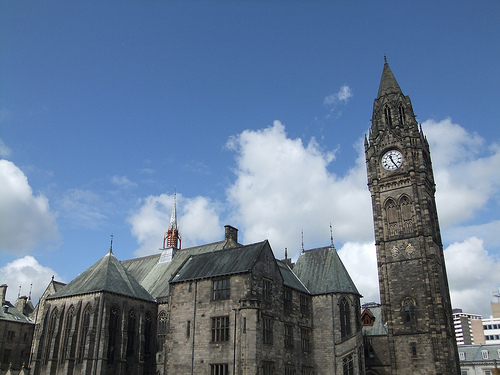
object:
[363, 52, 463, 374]
building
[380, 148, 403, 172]
clock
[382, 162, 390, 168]
roman numbers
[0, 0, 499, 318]
sky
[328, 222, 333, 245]
antenae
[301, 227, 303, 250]
antenae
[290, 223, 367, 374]
building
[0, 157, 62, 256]
clouds patch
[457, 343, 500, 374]
building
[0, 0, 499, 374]
town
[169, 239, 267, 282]
roof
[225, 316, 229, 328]
window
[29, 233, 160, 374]
building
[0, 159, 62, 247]
cloud